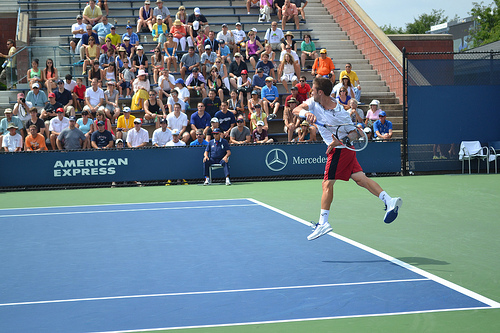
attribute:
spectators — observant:
[1, 0, 393, 155]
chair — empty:
[457, 138, 484, 172]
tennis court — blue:
[4, 195, 490, 332]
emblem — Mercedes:
[259, 145, 295, 182]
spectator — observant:
[186, 104, 213, 134]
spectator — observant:
[246, 85, 268, 117]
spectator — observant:
[229, 51, 248, 79]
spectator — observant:
[115, 46, 128, 70]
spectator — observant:
[290, 71, 310, 104]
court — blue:
[1, 195, 487, 332]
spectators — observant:
[78, 21, 303, 125]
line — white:
[133, 267, 303, 319]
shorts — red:
[320, 146, 365, 183]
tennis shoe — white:
[379, 195, 406, 222]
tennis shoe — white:
[305, 220, 330, 245]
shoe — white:
[302, 216, 337, 244]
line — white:
[252, 173, 499, 303]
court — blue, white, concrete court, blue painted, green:
[0, 172, 500, 330]